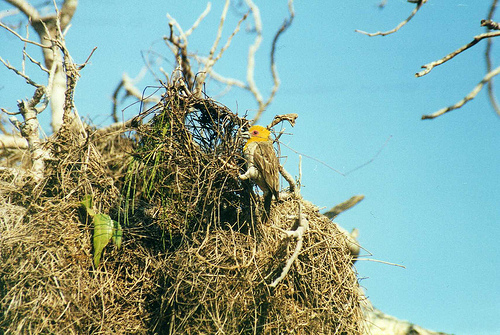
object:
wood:
[3, 0, 118, 185]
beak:
[241, 131, 251, 139]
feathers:
[252, 142, 279, 201]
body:
[242, 142, 278, 196]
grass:
[1, 85, 373, 333]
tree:
[110, 0, 298, 128]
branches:
[110, 0, 294, 126]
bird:
[235, 125, 279, 224]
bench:
[128, 87, 235, 242]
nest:
[0, 99, 361, 335]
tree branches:
[352, 1, 499, 121]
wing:
[254, 142, 281, 202]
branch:
[267, 164, 307, 288]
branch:
[164, 7, 193, 78]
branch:
[246, 4, 268, 117]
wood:
[263, 215, 310, 288]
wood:
[415, 17, 497, 82]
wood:
[409, 57, 498, 122]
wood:
[179, 3, 301, 122]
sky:
[297, 126, 499, 198]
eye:
[251, 130, 260, 136]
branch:
[420, 65, 498, 120]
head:
[241, 124, 271, 141]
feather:
[260, 141, 275, 156]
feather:
[268, 157, 279, 169]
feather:
[262, 170, 269, 185]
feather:
[271, 180, 281, 195]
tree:
[3, 0, 97, 139]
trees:
[111, 2, 498, 334]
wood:
[327, 0, 498, 129]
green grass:
[113, 126, 173, 250]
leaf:
[79, 194, 122, 269]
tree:
[0, 0, 373, 331]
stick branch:
[266, 201, 310, 288]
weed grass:
[1, 60, 368, 333]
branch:
[414, 33, 485, 77]